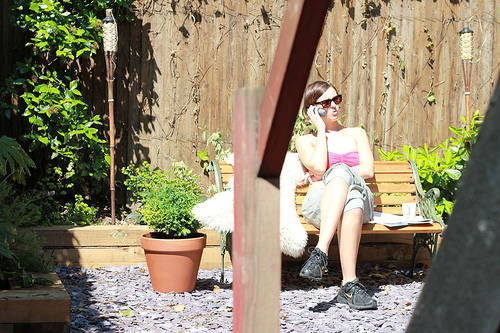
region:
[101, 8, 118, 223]
torch by the fence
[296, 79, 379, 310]
woman talking on the phone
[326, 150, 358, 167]
pink shirt on a woman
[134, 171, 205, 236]
green plant by the bench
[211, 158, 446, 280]
wooden bench under the sun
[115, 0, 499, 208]
wooden fence behind the bench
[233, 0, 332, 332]
red column in front of woman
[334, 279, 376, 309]
black sports shoe on a woman's foot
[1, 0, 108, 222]
green plants by the fence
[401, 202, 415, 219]
white cup on the bench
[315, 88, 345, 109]
She is wearing sun glasses.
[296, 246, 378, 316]
The shoes are black.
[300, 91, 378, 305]
She is sitting.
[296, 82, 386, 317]
She is talking on the phone.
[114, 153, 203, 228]
The bush is green.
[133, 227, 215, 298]
The pot is brown.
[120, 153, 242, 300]
The plant is next to the bench.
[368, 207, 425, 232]
The papers are on the bench.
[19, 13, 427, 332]
The sun is shining.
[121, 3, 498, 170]
The fence is brown.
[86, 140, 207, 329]
a brown flower pot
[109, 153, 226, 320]
a flower pot on the ground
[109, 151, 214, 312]
a green plant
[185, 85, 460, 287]
a woman sitting on a bench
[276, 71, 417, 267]
a woman on the phone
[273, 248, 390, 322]
black nike athletic sneakers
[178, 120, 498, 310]
a brown wooden bench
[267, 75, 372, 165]
a woman wearing sunglasses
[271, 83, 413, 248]
a woman wearing a pink top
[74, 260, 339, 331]
gray rocks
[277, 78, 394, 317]
Woman sitting on a bench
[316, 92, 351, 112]
Glasses on the woman's face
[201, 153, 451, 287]
Bench behind the woman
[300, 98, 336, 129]
Phone in woman's hand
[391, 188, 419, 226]
Cup on the bench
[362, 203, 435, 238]
Papers on the bench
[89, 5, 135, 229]
Torch in the dirt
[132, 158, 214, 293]
Flowerpot on the ground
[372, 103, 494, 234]
Plants behind the bench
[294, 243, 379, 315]
Black shoes on woman's feet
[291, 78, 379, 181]
Woman talking on the phone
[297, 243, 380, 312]
A pair of black shoes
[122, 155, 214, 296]
Green plant in a pot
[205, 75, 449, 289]
Woman sitting on a bench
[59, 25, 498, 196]
Brown fence behind the bench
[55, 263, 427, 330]
Gray rocks on the ground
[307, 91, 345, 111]
A pair of sunglasses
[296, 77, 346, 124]
Woman has brown hair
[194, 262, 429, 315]
Shadows on the ground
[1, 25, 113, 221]
Green leaves on a tree